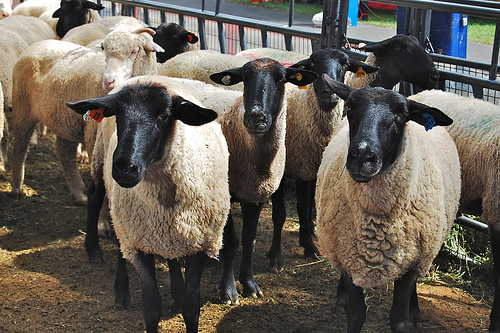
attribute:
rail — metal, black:
[181, 6, 335, 58]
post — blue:
[394, 2, 466, 95]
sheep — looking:
[87, 41, 429, 261]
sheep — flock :
[408, 85, 496, 330]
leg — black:
[340, 276, 368, 328]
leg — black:
[385, 275, 415, 326]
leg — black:
[294, 179, 319, 257]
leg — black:
[265, 193, 286, 264]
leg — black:
[482, 226, 496, 330]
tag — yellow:
[219, 72, 232, 85]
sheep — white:
[65, 76, 231, 331]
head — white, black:
[313, 68, 454, 183]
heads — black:
[77, 49, 438, 188]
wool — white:
[101, 83, 228, 271]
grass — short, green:
[243, 1, 498, 42]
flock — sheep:
[0, 0, 498, 330]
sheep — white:
[80, 52, 326, 303]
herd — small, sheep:
[4, 0, 496, 330]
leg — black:
[135, 250, 170, 331]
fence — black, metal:
[86, 0, 499, 287]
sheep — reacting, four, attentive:
[297, 71, 477, 300]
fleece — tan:
[361, 177, 376, 239]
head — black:
[68, 81, 218, 189]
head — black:
[211, 58, 319, 134]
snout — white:
[101, 56, 135, 92]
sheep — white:
[5, 19, 169, 214]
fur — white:
[19, 30, 161, 136]